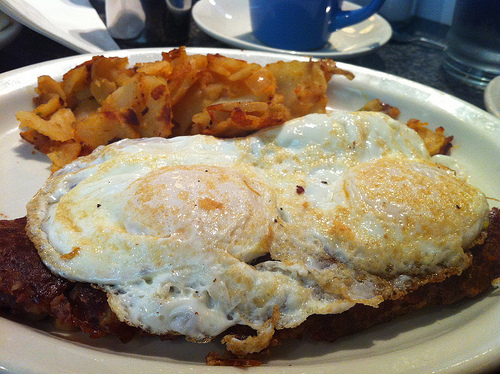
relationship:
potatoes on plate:
[58, 63, 322, 130] [0, 43, 493, 372]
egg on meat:
[25, 110, 493, 360] [2, 225, 493, 324]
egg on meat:
[37, 161, 267, 288] [2, 225, 493, 324]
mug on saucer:
[251, 0, 392, 45] [189, 1, 415, 56]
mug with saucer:
[251, 0, 392, 45] [189, 1, 415, 56]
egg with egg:
[25, 110, 493, 360] [37, 161, 267, 288]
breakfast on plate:
[20, 65, 481, 314] [0, 43, 493, 372]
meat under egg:
[2, 225, 493, 324] [25, 110, 493, 360]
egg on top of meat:
[25, 110, 493, 360] [2, 225, 493, 324]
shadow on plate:
[285, 298, 468, 342] [0, 43, 493, 372]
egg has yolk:
[25, 110, 493, 360] [335, 163, 465, 251]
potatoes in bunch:
[58, 63, 322, 130] [104, 51, 210, 132]